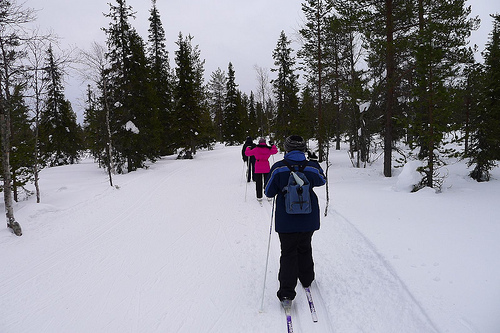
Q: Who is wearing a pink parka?
A: A skier.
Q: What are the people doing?
A: Cross country skiing.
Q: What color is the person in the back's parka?
A: Blue.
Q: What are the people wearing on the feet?
A: Skis.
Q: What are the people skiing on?
A: Snow.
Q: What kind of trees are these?
A: Evergreens.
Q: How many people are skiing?
A: Three.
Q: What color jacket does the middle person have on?
A: Pink.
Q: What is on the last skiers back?
A: Backpack.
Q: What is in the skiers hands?
A: Poles.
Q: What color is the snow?
A: White.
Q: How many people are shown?
A: 3.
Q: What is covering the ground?
A: Snow.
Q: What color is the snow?
A: White.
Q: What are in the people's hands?
A: Ski poles.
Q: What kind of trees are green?
A: Pine.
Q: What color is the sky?
A: White.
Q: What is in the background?
A: Trees.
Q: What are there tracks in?
A: The snow.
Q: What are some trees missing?
A: Leaves.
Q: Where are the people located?
A: In a forest.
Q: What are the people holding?
A: Ski poles.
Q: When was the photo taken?
A: Daytime.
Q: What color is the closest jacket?
A: Blue.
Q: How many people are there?
A: 3.